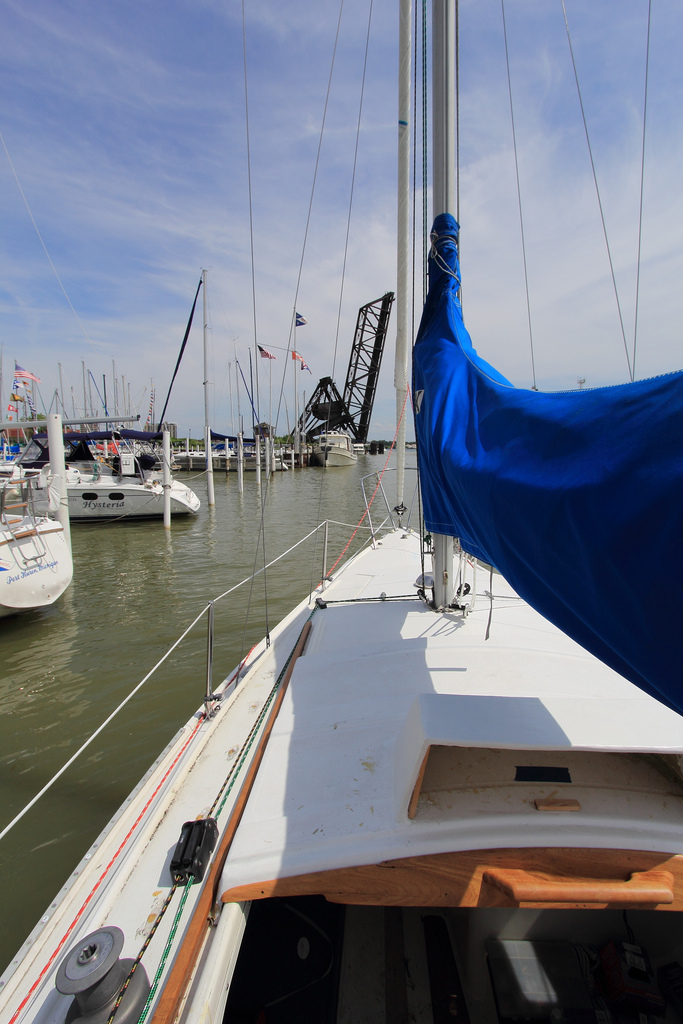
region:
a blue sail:
[415, 220, 681, 713]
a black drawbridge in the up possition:
[311, 291, 392, 451]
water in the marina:
[10, 453, 410, 973]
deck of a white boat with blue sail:
[3, 522, 674, 1017]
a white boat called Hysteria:
[5, 275, 203, 511]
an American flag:
[12, 360, 38, 382]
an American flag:
[254, 341, 275, 358]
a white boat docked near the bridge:
[312, 431, 357, 466]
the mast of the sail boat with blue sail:
[398, 3, 468, 612]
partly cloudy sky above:
[1, 1, 676, 428]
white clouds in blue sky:
[54, 5, 174, 151]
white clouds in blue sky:
[250, 146, 323, 222]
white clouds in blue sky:
[505, 96, 581, 160]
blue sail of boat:
[376, 266, 680, 700]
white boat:
[101, 536, 680, 896]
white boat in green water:
[19, 416, 92, 632]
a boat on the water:
[0, 2, 679, 1019]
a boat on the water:
[11, 440, 193, 520]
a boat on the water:
[179, 437, 285, 474]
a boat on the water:
[315, 427, 364, 469]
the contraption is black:
[176, 810, 224, 893]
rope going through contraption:
[144, 816, 231, 943]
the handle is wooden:
[489, 846, 666, 939]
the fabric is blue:
[419, 313, 665, 688]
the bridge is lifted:
[352, 288, 394, 436]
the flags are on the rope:
[3, 359, 35, 433]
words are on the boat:
[80, 494, 134, 521]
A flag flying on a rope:
[291, 308, 308, 328]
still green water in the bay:
[97, 569, 150, 612]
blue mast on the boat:
[396, 274, 636, 565]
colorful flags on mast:
[225, 298, 336, 392]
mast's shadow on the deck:
[260, 577, 478, 705]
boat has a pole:
[204, 600, 212, 706]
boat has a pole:
[264, 567, 266, 640]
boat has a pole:
[431, 528, 458, 609]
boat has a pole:
[398, 8, 409, 527]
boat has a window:
[83, 493, 103, 503]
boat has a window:
[78, 491, 99, 498]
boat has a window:
[107, 492, 126, 502]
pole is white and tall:
[45, 415, 73, 571]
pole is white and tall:
[161, 426, 169, 530]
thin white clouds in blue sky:
[3, 2, 680, 441]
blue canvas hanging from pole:
[409, 0, 680, 715]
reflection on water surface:
[0, 449, 422, 970]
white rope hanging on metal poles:
[0, 518, 388, 973]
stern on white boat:
[2, 505, 72, 619]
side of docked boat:
[0, 468, 200, 525]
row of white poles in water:
[47, 415, 278, 562]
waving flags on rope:
[5, 362, 40, 425]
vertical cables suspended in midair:
[238, 1, 653, 684]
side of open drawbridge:
[288, 293, 393, 447]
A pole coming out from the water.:
[190, 259, 217, 521]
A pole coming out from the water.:
[162, 423, 176, 545]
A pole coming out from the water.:
[45, 404, 87, 586]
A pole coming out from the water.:
[200, 426, 228, 515]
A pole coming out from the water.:
[232, 422, 249, 497]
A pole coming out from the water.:
[253, 430, 273, 488]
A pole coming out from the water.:
[266, 434, 272, 486]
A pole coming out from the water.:
[266, 439, 282, 488]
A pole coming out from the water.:
[82, 358, 93, 427]